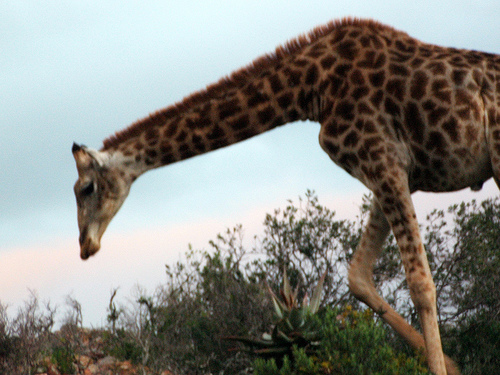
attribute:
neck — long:
[130, 29, 322, 177]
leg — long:
[373, 167, 448, 375]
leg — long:
[348, 192, 462, 374]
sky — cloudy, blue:
[2, 0, 499, 326]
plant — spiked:
[221, 264, 346, 375]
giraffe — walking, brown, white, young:
[72, 17, 500, 375]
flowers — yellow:
[318, 295, 374, 375]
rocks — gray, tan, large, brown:
[46, 327, 154, 375]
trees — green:
[170, 187, 500, 375]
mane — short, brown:
[102, 15, 389, 151]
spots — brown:
[123, 28, 499, 196]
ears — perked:
[71, 141, 103, 173]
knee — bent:
[348, 259, 379, 309]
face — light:
[74, 170, 100, 261]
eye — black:
[82, 180, 95, 197]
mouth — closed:
[84, 236, 92, 258]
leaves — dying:
[140, 187, 494, 303]